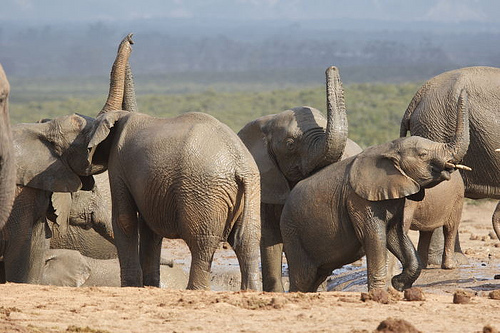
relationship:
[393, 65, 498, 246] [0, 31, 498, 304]
elephant in herd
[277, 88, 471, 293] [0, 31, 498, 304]
elephant in herd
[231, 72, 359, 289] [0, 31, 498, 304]
elephant in herd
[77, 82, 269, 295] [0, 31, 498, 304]
elephant in herd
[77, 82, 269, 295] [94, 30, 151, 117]
elephant touching trunks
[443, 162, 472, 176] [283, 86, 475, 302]
tusks on small elephant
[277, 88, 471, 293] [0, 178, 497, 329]
elephant playing in mud hole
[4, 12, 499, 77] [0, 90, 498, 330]
hill behind land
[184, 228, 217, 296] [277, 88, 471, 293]
leg on elephant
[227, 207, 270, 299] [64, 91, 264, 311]
leg on elephant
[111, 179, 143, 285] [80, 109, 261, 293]
leg on elephant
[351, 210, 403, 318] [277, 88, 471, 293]
leg on elephant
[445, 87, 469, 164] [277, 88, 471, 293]
trunk on elephant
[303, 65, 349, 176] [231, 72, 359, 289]
trunk on elephant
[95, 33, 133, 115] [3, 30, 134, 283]
trunk on elephant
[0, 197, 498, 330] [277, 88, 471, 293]
dirt under elephant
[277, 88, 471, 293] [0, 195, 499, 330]
elephant in mud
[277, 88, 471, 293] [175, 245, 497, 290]
elephant standing in mud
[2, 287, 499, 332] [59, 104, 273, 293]
ground under elephant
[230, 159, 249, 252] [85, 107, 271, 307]
tail on elephant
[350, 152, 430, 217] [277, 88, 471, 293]
ear on elephant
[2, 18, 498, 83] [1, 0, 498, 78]
trees covered in fog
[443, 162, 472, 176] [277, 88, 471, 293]
tusks of an elephant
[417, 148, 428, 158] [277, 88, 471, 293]
eye of elephant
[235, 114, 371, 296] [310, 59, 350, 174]
elephant with raised trunk